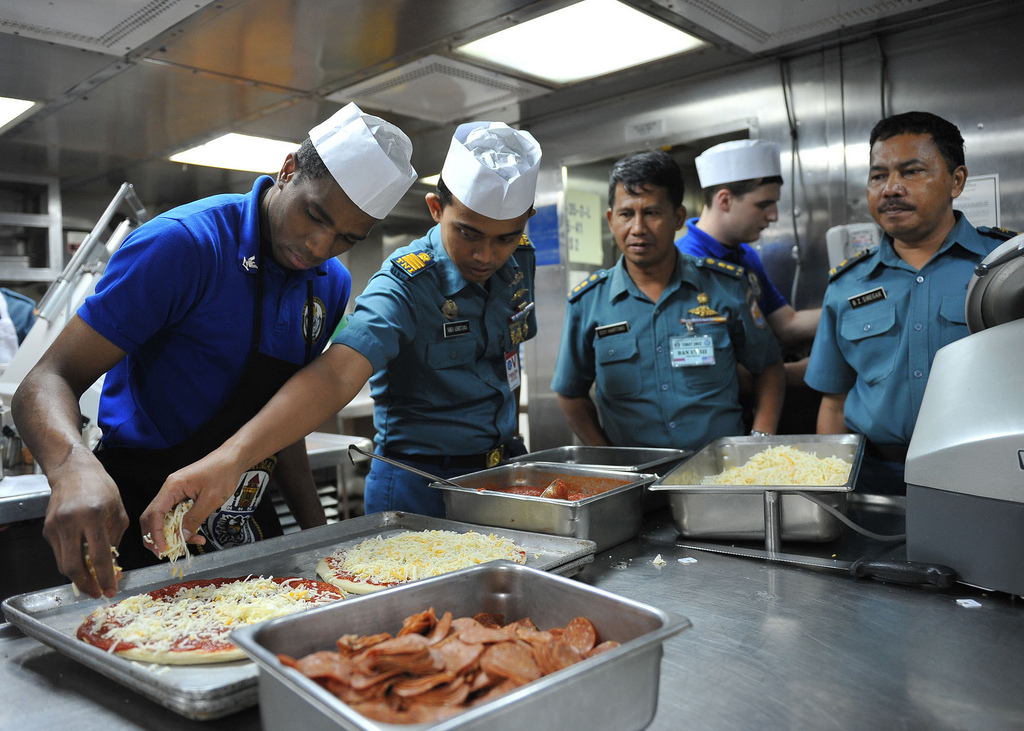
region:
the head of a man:
[251, 107, 373, 303]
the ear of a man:
[257, 139, 303, 197]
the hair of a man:
[283, 142, 332, 200]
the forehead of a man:
[310, 189, 374, 232]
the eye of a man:
[295, 195, 371, 256]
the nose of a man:
[304, 215, 353, 264]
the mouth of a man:
[260, 236, 324, 282]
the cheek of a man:
[269, 195, 304, 241]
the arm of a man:
[0, 198, 184, 578]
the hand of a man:
[49, 458, 148, 595]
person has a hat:
[305, 98, 416, 217]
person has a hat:
[441, 119, 541, 224]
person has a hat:
[693, 138, 780, 189]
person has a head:
[270, 141, 375, 271]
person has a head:
[424, 180, 536, 280]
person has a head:
[601, 151, 690, 269]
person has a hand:
[38, 470, 131, 603]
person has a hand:
[139, 461, 231, 559]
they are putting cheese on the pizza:
[28, 443, 291, 636]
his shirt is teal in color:
[622, 372, 680, 421]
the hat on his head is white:
[720, 136, 762, 174]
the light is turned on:
[527, 25, 619, 76]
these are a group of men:
[2, 60, 1017, 694]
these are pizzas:
[8, 312, 657, 663]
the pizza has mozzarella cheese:
[125, 519, 566, 630]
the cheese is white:
[114, 487, 465, 677]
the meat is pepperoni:
[273, 545, 485, 710]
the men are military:
[51, 175, 903, 527]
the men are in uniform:
[124, 49, 915, 407]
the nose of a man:
[245, 116, 420, 294]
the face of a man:
[409, 136, 572, 314]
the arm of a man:
[160, 195, 522, 560]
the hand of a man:
[122, 435, 253, 633]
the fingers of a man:
[52, 458, 174, 613]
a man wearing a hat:
[228, 43, 432, 268]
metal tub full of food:
[220, 530, 705, 728]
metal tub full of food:
[226, 543, 705, 728]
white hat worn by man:
[277, 89, 429, 244]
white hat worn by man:
[438, 104, 543, 206]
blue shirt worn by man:
[87, 203, 288, 437]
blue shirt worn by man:
[377, 227, 499, 452]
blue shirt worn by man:
[544, 259, 710, 405]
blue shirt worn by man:
[819, 236, 918, 388]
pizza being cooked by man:
[55, 511, 330, 709]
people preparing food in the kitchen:
[81, 51, 906, 707]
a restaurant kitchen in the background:
[39, 37, 981, 644]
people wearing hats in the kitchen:
[81, 60, 923, 668]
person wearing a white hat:
[30, 66, 474, 654]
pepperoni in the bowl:
[284, 492, 930, 721]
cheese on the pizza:
[62, 386, 654, 697]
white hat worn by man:
[295, 63, 423, 244]